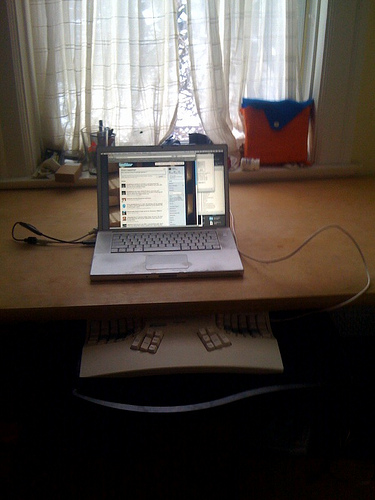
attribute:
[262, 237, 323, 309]
white cord — is plugged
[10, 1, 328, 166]
curtains — white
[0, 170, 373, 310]
table — Light brown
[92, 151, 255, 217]
laptop — grey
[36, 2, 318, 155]
curtains — white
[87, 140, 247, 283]
laptop — dark silver, on, grey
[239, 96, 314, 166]
bag — orange, blue